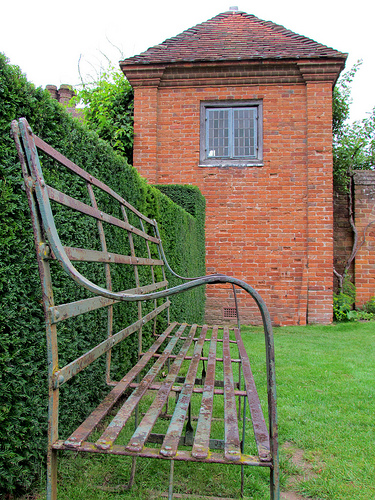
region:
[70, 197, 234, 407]
this is a bench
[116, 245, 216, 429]
the bench is metalic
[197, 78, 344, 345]
this is a house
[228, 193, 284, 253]
this is a wall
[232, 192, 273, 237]
the wall is brown in color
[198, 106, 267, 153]
this is a window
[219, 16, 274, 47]
this is the roof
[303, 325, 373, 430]
this is a grass area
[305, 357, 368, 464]
the grass is green in color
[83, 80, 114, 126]
this is a tree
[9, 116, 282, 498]
rusty metal bench sitting on top of grass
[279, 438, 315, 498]
gray bare patch worn into the grass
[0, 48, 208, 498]
green hedge behind bench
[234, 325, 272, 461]
metal slat welded to bench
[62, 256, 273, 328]
curved metal armrest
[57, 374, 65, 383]
metal bolts on bench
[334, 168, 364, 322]
vine growing on red brick wall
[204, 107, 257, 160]
window is closed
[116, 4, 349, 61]
red tile roof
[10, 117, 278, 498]
bench is in front of the hedge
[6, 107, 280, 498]
a worn green metal bench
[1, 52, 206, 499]
a cut green head behind a bench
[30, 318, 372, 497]
a green lawn around a bench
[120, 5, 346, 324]
a red brick building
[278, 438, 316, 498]
a patch of dirt in the grass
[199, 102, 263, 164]
a shuttered window in a building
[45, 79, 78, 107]
two chimneys peeking over the top of a hedge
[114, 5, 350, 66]
the roof of a brick building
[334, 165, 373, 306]
a high brick wall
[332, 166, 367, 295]
a tree next to a brick wall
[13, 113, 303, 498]
Rot iron bench in grass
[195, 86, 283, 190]
Small window on building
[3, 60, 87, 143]
Part of a green hedge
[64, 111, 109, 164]
Part of a green hedge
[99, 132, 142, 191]
Part of a green hedge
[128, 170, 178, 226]
Part of a green hedge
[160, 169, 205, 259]
Part of a green hedge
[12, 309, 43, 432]
Part of a green hedge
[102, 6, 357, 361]
Large red brick building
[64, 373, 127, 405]
Part of a green hedge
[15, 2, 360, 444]
a yard in the countryside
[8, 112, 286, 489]
bare metal bench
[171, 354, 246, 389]
rust on the seat of the bench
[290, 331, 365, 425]
closely cut green grass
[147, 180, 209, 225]
well-trimmed hedge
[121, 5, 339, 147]
old brick building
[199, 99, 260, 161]
shutter windows with many panes of glass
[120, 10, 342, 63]
worn tile roof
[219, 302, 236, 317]
small vent surrounded by brick work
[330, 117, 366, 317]
tree growing on the side of the building